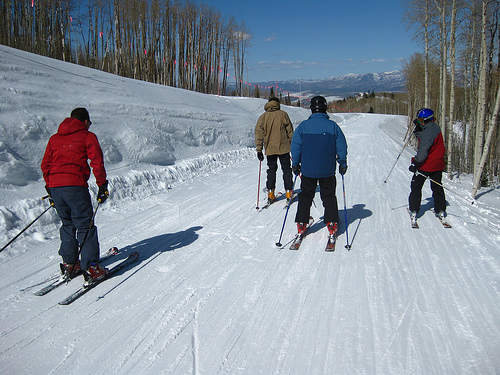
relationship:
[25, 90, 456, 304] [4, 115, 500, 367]
people skiing in field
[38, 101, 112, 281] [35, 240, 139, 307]
man on skiingboards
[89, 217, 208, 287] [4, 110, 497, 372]
shadow on floor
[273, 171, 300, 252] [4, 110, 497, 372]
skiing stick on floor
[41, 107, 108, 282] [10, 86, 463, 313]
man in group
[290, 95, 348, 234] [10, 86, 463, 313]
people in group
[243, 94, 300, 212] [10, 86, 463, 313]
person in group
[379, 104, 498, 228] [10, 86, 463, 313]
person in group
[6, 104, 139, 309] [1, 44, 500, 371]
skier on snow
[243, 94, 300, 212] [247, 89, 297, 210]
skier on snow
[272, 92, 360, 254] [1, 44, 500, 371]
skier on snow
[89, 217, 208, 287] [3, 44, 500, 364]
shadow on ground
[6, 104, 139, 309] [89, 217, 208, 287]
skier has shadow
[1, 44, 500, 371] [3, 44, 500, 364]
snow on ground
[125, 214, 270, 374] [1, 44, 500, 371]
track in snow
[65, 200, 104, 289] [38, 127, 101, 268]
ski pole behind body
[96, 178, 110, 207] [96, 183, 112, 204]
glove on hand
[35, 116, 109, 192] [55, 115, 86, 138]
jacket has hood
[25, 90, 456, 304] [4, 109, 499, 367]
people on ski trail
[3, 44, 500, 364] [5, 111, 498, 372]
ground has tracks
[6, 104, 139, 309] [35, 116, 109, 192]
skier has jacket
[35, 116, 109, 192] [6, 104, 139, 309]
jacket on skier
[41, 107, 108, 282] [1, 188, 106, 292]
man holding ski poles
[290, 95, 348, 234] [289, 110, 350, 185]
people has jacket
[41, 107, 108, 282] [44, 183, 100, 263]
man has pants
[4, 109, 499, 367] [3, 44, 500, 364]
ski trail on ground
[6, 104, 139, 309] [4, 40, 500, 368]
skier on slope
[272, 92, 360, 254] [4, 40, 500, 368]
skier on slope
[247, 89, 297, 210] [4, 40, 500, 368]
skier on slope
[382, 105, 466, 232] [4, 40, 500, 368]
skier on slope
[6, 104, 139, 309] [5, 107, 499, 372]
skier on trail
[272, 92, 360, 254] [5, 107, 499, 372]
skier on trail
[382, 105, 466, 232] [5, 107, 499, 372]
skier on trail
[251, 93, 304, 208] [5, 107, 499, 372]
skier on trail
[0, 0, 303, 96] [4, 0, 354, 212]
markers in area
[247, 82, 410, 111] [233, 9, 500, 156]
trees in distance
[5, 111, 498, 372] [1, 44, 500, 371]
tracks in snow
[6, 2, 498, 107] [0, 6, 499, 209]
scenery in background